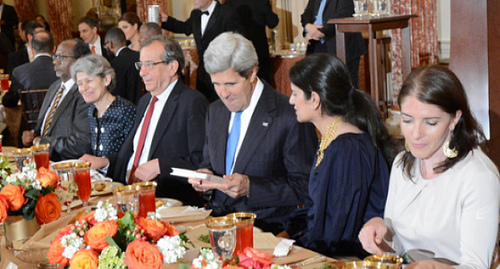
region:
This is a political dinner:
[22, 31, 458, 266]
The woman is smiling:
[54, 51, 131, 129]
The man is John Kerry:
[152, 27, 266, 152]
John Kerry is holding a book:
[178, 27, 265, 202]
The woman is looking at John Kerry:
[269, 43, 356, 149]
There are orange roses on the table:
[11, 147, 293, 267]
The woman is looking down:
[380, 68, 475, 155]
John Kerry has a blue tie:
[210, 67, 269, 190]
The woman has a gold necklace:
[290, 99, 353, 171]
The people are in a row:
[23, 29, 493, 232]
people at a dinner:
[0, 0, 498, 268]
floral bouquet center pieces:
[0, 163, 221, 266]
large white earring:
[442, 136, 459, 159]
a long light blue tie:
[222, 108, 244, 175]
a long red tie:
[127, 93, 159, 183]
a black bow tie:
[196, 8, 213, 18]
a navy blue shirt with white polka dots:
[86, 96, 136, 161]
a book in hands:
[168, 163, 252, 200]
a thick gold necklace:
[314, 113, 342, 161]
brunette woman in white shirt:
[354, 61, 499, 267]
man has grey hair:
[204, 42, 242, 64]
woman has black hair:
[302, 59, 337, 86]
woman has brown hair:
[420, 70, 449, 95]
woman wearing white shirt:
[400, 186, 447, 218]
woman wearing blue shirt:
[327, 163, 353, 220]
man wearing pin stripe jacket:
[266, 134, 291, 178]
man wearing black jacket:
[173, 106, 191, 143]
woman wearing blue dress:
[108, 114, 125, 134]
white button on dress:
[98, 124, 108, 136]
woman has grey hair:
[75, 61, 100, 71]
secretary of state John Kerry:
[203, 33, 260, 113]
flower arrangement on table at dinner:
[69, 220, 181, 262]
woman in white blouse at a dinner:
[378, 61, 496, 256]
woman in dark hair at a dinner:
[284, 50, 393, 243]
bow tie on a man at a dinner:
[192, 4, 216, 20]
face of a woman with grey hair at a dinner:
[72, 55, 118, 105]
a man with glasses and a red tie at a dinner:
[124, 34, 203, 182]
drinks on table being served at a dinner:
[71, 162, 103, 209]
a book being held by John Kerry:
[164, 154, 246, 192]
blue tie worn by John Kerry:
[214, 105, 248, 178]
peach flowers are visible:
[1, 162, 75, 236]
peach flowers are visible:
[52, 210, 150, 265]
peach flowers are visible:
[5, 130, 126, 258]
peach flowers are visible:
[30, 157, 114, 241]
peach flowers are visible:
[51, 171, 138, 236]